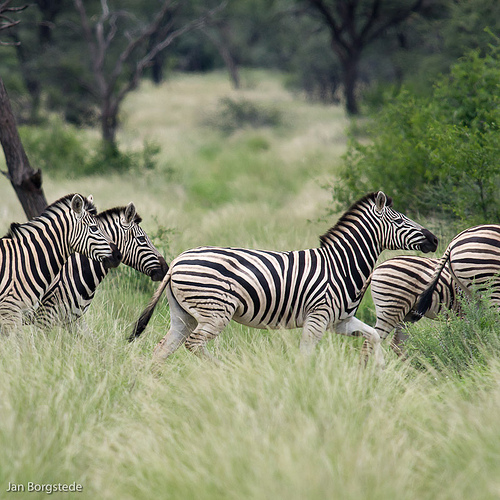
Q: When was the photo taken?
A: Daytime.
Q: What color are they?
A: Black and white.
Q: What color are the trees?
A: Green.